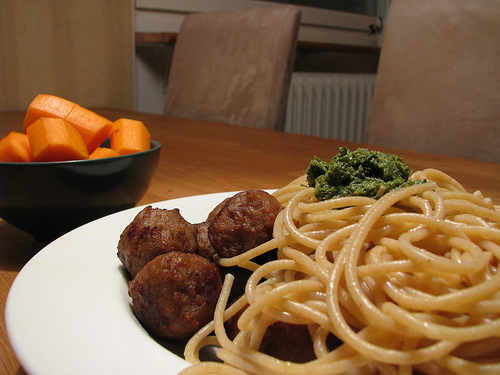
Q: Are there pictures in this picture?
A: No, there are no pictures.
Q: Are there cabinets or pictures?
A: No, there are no pictures or cabinets.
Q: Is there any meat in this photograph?
A: Yes, there is meat.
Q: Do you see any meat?
A: Yes, there is meat.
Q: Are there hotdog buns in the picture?
A: No, there are no hotdog buns.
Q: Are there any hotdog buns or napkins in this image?
A: No, there are no hotdog buns or napkins.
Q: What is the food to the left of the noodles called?
A: The food is meat.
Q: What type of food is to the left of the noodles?
A: The food is meat.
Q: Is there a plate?
A: Yes, there is a plate.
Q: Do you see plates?
A: Yes, there is a plate.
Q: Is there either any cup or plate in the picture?
A: Yes, there is a plate.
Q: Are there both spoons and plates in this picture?
A: No, there is a plate but no spoons.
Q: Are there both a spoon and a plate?
A: No, there is a plate but no spoons.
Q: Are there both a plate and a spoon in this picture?
A: No, there is a plate but no spoons.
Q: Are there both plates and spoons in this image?
A: No, there is a plate but no spoons.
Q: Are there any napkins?
A: No, there are no napkins.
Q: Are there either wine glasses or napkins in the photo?
A: No, there are no napkins or wine glasses.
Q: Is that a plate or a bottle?
A: That is a plate.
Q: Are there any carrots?
A: Yes, there is a carrot.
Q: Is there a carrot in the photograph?
A: Yes, there is a carrot.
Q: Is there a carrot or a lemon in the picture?
A: Yes, there is a carrot.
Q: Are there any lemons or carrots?
A: Yes, there is a carrot.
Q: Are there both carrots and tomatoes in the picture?
A: No, there is a carrot but no tomatoes.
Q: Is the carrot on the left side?
A: Yes, the carrot is on the left of the image.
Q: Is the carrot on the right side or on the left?
A: The carrot is on the left of the image.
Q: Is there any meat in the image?
A: Yes, there is meat.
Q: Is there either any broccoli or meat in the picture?
A: Yes, there is meat.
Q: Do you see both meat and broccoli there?
A: No, there is meat but no broccoli.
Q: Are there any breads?
A: No, there are no breads.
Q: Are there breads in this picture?
A: No, there are no breads.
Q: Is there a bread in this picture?
A: No, there is no breads.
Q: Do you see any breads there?
A: No, there are no breads.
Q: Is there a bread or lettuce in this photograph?
A: No, there are no breads or lettuce.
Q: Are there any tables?
A: Yes, there is a table.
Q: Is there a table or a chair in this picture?
A: Yes, there is a table.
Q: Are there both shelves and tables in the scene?
A: No, there is a table but no shelves.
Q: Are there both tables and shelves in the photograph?
A: No, there is a table but no shelves.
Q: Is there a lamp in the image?
A: No, there are no lamps.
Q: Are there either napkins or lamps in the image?
A: No, there are no lamps or napkins.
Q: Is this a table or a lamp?
A: This is a table.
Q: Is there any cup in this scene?
A: No, there are no cups.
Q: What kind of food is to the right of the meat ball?
A: The food is noodles.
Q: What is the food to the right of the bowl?
A: The food is noodles.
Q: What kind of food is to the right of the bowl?
A: The food is noodles.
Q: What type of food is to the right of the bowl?
A: The food is noodles.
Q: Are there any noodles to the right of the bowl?
A: Yes, there are noodles to the right of the bowl.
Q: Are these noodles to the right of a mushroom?
A: No, the noodles are to the right of the bowl.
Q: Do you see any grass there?
A: Yes, there is grass.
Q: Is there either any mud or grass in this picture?
A: Yes, there is grass.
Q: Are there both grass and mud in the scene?
A: No, there is grass but no mud.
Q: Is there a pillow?
A: No, there are no pillows.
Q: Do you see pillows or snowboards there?
A: No, there are no pillows or snowboards.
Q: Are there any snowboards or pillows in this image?
A: No, there are no pillows or snowboards.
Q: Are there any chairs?
A: Yes, there is a chair.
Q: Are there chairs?
A: Yes, there is a chair.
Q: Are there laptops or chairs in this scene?
A: Yes, there is a chair.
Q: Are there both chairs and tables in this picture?
A: Yes, there are both a chair and a table.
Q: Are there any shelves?
A: No, there are no shelves.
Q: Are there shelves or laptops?
A: No, there are no shelves or laptops.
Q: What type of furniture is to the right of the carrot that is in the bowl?
A: The piece of furniture is a chair.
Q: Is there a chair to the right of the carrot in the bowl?
A: Yes, there is a chair to the right of the carrot.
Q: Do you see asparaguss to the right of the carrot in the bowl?
A: No, there is a chair to the right of the carrot.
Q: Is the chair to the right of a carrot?
A: Yes, the chair is to the right of a carrot.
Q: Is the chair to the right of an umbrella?
A: No, the chair is to the right of a carrot.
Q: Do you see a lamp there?
A: No, there are no lamps.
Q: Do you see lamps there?
A: No, there are no lamps.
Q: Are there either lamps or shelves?
A: No, there are no lamps or shelves.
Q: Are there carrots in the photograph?
A: Yes, there is a carrot.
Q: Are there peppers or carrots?
A: Yes, there is a carrot.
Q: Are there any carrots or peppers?
A: Yes, there is a carrot.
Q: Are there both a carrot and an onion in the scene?
A: No, there is a carrot but no onions.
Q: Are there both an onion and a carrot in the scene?
A: No, there is a carrot but no onions.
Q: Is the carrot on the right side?
A: No, the carrot is on the left of the image.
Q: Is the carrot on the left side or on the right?
A: The carrot is on the left of the image.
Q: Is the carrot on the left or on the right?
A: The carrot is on the left of the image.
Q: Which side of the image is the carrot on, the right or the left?
A: The carrot is on the left of the image.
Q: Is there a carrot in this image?
A: Yes, there is a carrot.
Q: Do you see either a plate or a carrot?
A: Yes, there is a carrot.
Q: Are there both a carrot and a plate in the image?
A: Yes, there are both a carrot and a plate.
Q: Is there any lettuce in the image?
A: No, there is no lettuce.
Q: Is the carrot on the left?
A: Yes, the carrot is on the left of the image.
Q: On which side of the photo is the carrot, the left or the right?
A: The carrot is on the left of the image.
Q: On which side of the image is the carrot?
A: The carrot is on the left of the image.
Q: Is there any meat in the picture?
A: Yes, there is meat.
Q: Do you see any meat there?
A: Yes, there is meat.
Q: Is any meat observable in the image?
A: Yes, there is meat.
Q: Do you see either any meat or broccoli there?
A: Yes, there is meat.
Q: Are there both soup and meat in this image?
A: No, there is meat but no soup.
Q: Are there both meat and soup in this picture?
A: No, there is meat but no soup.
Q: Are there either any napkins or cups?
A: No, there are no napkins or cups.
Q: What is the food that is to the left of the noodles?
A: The food is meat.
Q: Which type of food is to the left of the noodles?
A: The food is meat.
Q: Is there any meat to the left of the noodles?
A: Yes, there is meat to the left of the noodles.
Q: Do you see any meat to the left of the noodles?
A: Yes, there is meat to the left of the noodles.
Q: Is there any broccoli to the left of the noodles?
A: No, there is meat to the left of the noodles.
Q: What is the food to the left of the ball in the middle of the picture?
A: The food is meat.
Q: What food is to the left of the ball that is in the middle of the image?
A: The food is meat.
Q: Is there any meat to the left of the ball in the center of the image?
A: Yes, there is meat to the left of the ball.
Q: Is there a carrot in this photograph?
A: Yes, there is a carrot.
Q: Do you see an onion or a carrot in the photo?
A: Yes, there is a carrot.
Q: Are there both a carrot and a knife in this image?
A: No, there is a carrot but no knives.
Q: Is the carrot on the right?
A: No, the carrot is on the left of the image.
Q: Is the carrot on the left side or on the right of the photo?
A: The carrot is on the left of the image.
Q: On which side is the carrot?
A: The carrot is on the left of the image.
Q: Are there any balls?
A: Yes, there is a ball.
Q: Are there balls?
A: Yes, there is a ball.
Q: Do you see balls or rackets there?
A: Yes, there is a ball.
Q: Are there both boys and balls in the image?
A: No, there is a ball but no boys.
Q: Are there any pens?
A: No, there are no pens.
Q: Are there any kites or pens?
A: No, there are no pens or kites.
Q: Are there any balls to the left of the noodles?
A: Yes, there is a ball to the left of the noodles.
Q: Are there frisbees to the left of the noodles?
A: No, there is a ball to the left of the noodles.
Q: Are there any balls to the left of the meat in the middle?
A: Yes, there is a ball to the left of the meat.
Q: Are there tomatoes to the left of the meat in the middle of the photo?
A: No, there is a ball to the left of the meat.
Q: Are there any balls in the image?
A: Yes, there is a ball.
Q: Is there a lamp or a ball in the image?
A: Yes, there is a ball.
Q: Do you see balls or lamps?
A: Yes, there is a ball.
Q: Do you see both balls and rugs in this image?
A: No, there is a ball but no rugs.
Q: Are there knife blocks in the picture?
A: No, there are no knife blocks.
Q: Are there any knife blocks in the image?
A: No, there are no knife blocks.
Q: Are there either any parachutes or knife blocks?
A: No, there are no knife blocks or parachutes.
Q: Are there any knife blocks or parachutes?
A: No, there are no knife blocks or parachutes.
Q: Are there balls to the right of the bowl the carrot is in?
A: Yes, there is a ball to the right of the bowl.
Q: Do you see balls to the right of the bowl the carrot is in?
A: Yes, there is a ball to the right of the bowl.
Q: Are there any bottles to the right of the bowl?
A: No, there is a ball to the right of the bowl.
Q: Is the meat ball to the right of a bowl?
A: Yes, the ball is to the right of a bowl.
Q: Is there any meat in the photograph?
A: Yes, there is meat.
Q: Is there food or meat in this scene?
A: Yes, there is meat.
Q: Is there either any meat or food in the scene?
A: Yes, there is meat.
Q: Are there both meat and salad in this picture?
A: No, there is meat but no salad.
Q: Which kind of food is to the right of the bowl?
A: The food is meat.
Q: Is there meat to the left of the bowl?
A: No, the meat is to the right of the bowl.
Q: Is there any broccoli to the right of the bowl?
A: No, there is meat to the right of the bowl.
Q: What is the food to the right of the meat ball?
A: The food is meat.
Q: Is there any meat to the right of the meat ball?
A: Yes, there is meat to the right of the ball.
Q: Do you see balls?
A: Yes, there is a ball.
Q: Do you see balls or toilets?
A: Yes, there is a ball.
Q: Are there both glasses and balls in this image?
A: No, there is a ball but no glasses.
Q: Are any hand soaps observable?
A: No, there are no hand soaps.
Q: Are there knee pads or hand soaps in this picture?
A: No, there are no hand soaps or knee pads.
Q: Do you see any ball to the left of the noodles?
A: Yes, there is a ball to the left of the noodles.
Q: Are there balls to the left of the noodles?
A: Yes, there is a ball to the left of the noodles.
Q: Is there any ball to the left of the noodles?
A: Yes, there is a ball to the left of the noodles.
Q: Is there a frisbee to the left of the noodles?
A: No, there is a ball to the left of the noodles.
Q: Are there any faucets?
A: No, there are no faucets.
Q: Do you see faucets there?
A: No, there are no faucets.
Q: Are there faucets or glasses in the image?
A: No, there are no faucets or glasses.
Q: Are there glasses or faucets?
A: No, there are no faucets or glasses.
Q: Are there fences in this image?
A: No, there are no fences.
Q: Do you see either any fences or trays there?
A: No, there are no fences or trays.